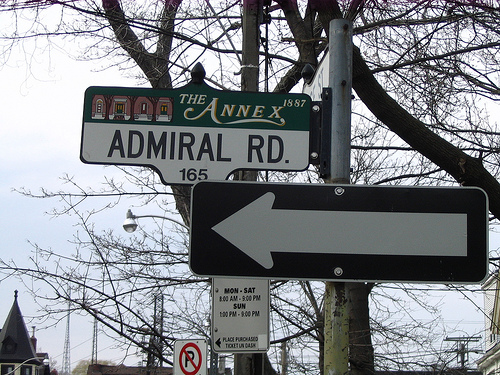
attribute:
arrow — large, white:
[211, 191, 467, 267]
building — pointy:
[0, 289, 52, 373]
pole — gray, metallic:
[327, 18, 352, 373]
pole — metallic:
[319, 17, 352, 373]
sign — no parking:
[174, 338, 208, 373]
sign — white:
[212, 274, 270, 354]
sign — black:
[189, 180, 489, 285]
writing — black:
[108, 128, 290, 180]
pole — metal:
[324, 20, 360, 370]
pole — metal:
[320, 18, 360, 373]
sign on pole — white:
[192, 283, 286, 328]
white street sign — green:
[210, 279, 277, 361]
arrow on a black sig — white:
[195, 176, 478, 254]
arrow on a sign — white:
[208, 191, 317, 280]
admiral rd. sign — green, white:
[108, 122, 298, 163]